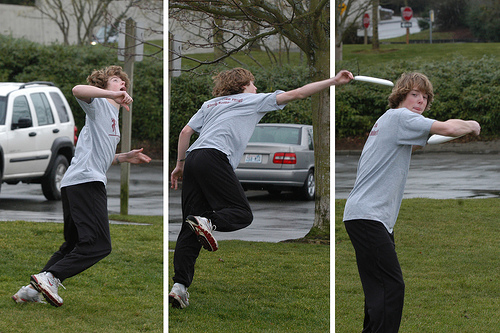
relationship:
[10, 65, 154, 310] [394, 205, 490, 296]
boy running on grass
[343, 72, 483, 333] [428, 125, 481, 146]
boy throwing frisbee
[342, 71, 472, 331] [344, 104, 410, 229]
boy wearing shirt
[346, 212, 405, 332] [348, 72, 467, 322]
pants on boy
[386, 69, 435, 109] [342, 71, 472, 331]
hair on boy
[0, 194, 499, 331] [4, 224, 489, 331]
green grass on ground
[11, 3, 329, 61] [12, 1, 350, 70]
branches on trees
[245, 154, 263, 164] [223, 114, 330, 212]
license plate on back of car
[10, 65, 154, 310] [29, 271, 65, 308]
boy wearing shoe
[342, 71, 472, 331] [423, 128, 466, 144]
boy throwing frisbee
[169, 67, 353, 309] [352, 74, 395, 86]
boy throwing frisbee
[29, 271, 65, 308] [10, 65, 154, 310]
shoe on boy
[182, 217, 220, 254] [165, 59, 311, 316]
shoe on boy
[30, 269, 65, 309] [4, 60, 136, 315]
shoe on boy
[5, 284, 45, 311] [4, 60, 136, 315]
shoe on boy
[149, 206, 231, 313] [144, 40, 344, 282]
shoes on boy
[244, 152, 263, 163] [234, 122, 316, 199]
license plate on car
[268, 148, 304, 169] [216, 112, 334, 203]
light on car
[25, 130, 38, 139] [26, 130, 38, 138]
handle of door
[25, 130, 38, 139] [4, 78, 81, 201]
handle on car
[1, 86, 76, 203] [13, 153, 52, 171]
suv with trim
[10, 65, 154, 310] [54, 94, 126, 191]
boy wearing shirt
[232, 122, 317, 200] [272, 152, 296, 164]
car with light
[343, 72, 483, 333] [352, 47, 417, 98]
boy throwing frisbee